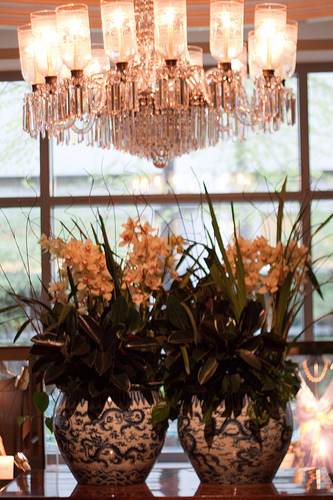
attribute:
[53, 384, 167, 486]
vase — white, blue, pottery, large, porcelain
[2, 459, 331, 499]
table — brown, wooden, a surface, shiny, smooth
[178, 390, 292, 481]
vase — blue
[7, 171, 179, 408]
flowers — partial, orchids, arrangment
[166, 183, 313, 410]
flowers — orchids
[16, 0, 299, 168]
chandelier — hanging, glass, crystal, crystal drop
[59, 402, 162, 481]
design — blue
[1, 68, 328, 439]
window — partial, framed, brown, wooden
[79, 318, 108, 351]
leaf — green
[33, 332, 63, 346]
leaf — green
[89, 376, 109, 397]
leaf — green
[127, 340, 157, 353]
leaf — green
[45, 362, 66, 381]
leaf — green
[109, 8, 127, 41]
light bulb — on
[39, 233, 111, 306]
flower — large, white, small, pink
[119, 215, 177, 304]
flower — white, pink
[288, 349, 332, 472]
mannequin reflection — black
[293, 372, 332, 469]
dress — white, reflection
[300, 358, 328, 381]
pearls — white, necklace, reflection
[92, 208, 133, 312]
leaf — long, green, tall, spiky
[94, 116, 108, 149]
pendant — crystal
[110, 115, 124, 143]
pendant — crystal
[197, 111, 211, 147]
pendant — round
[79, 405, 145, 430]
dragon — blue